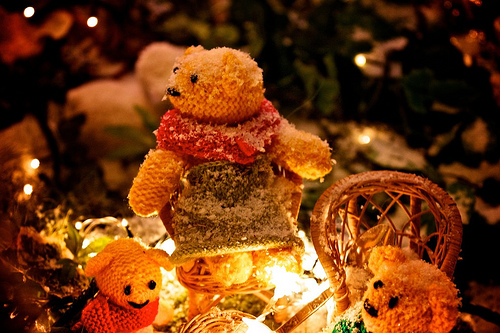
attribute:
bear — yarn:
[76, 239, 176, 332]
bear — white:
[1, 43, 197, 207]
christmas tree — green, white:
[288, 15, 469, 125]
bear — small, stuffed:
[106, 17, 421, 329]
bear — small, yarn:
[146, 28, 315, 269]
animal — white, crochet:
[119, 48, 302, 273]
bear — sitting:
[128, 45, 335, 215]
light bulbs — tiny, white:
[18, 154, 55, 201]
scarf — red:
[76, 295, 162, 332]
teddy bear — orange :
[106, 33, 388, 293]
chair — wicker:
[308, 166, 463, 310]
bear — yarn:
[326, 243, 463, 331]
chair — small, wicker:
[269, 157, 484, 287]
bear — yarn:
[128, 46, 335, 281]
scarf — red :
[156, 100, 286, 163]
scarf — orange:
[72, 292, 165, 328]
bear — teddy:
[89, 53, 318, 293]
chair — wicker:
[312, 139, 474, 306]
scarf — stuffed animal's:
[153, 107, 302, 159]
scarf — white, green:
[330, 305, 370, 332]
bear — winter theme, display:
[104, 38, 364, 318]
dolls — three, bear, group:
[107, 37, 450, 310]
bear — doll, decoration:
[160, 41, 338, 233]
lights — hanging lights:
[3, 2, 499, 84]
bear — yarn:
[72, 236, 175, 329]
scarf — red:
[139, 104, 296, 170]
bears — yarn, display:
[44, 45, 472, 331]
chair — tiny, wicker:
[308, 161, 468, 328]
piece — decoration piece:
[19, 52, 439, 332]